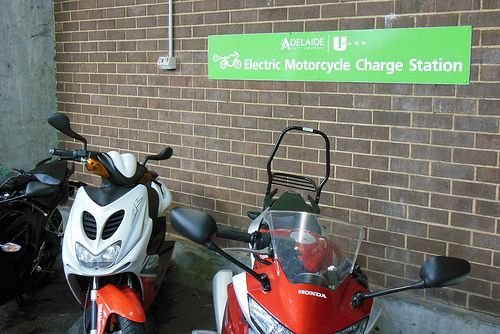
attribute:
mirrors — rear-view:
[416, 254, 474, 288]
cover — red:
[93, 281, 148, 332]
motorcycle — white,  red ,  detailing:
[0, 147, 75, 331]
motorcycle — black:
[1, 116, 110, 278]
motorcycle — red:
[170, 124, 472, 331]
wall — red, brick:
[359, 126, 488, 216]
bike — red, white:
[232, 150, 405, 325]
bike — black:
[0, 148, 70, 295]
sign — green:
[190, 14, 481, 112]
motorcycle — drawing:
[209, 51, 244, 73]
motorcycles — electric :
[18, 107, 475, 332]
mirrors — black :
[166, 202, 218, 244]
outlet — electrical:
[139, 43, 194, 92]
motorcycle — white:
[43, 144, 178, 332]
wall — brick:
[129, 30, 436, 217]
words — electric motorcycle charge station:
[240, 55, 468, 79]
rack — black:
[261, 124, 330, 208]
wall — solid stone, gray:
[2, 2, 58, 168]